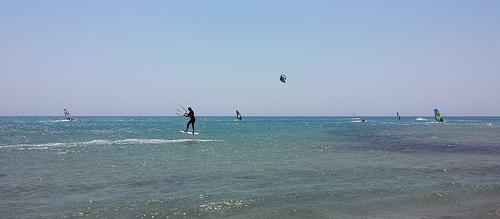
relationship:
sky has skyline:
[0, 1, 499, 117] [1, 111, 499, 121]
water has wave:
[0, 117, 499, 218] [0, 137, 223, 150]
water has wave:
[0, 117, 499, 218] [41, 119, 73, 123]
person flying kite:
[360, 117, 366, 123] [279, 74, 286, 83]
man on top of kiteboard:
[182, 106, 196, 135] [181, 130, 200, 135]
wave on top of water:
[0, 137, 223, 150] [0, 117, 499, 218]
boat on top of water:
[63, 109, 76, 121] [0, 117, 499, 218]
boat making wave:
[63, 109, 76, 121] [41, 119, 73, 123]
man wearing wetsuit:
[182, 106, 196, 135] [186, 110, 196, 131]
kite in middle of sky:
[279, 74, 286, 83] [0, 1, 499, 117]